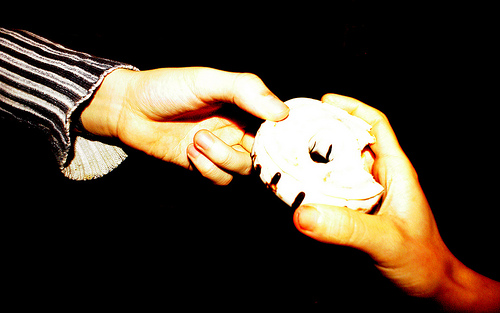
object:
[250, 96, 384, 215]
donut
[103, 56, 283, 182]
hand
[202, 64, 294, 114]
thumb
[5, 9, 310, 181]
person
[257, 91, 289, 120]
nail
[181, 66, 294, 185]
finger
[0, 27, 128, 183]
arm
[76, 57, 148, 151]
wrist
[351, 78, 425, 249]
knuckle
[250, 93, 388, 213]
donut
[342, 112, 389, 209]
bite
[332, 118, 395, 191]
part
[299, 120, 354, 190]
icing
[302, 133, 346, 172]
hole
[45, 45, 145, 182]
sleeve